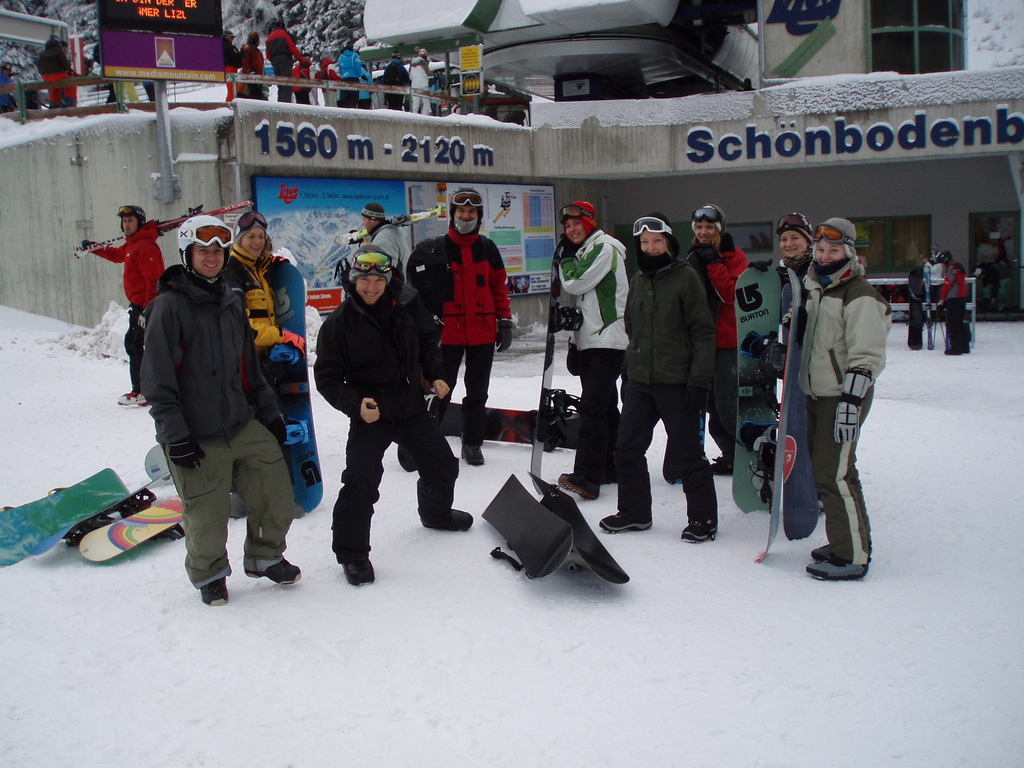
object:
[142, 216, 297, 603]
man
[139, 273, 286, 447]
jacket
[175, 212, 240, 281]
helmet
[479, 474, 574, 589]
snowboards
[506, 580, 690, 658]
snow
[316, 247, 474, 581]
man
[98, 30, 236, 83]
digital display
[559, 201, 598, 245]
cap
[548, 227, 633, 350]
jacket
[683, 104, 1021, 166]
resort name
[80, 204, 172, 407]
man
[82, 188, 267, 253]
skis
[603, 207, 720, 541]
girl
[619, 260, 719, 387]
jacket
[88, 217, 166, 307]
jacket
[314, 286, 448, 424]
jacket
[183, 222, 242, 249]
ski goggles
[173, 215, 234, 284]
head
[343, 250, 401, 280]
ski goggles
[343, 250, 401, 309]
person's head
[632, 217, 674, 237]
goggles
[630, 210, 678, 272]
head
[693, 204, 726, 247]
head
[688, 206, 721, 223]
goggles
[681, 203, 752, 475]
person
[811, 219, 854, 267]
head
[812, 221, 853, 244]
goggles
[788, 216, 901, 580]
person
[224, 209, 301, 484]
person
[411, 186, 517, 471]
person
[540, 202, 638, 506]
person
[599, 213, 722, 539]
person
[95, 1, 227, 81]
wall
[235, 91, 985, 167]
wall